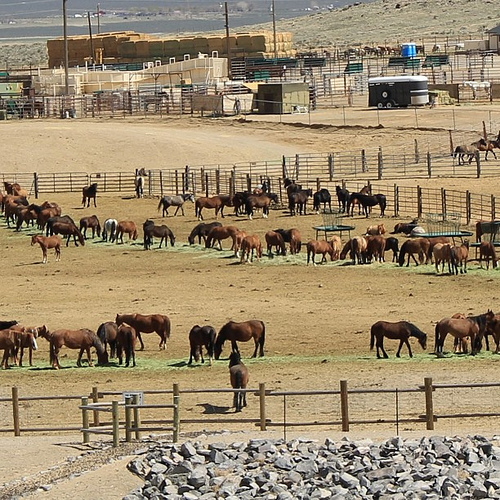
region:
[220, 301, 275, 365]
brown horse in pen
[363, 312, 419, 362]
brown horse in pen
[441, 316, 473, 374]
brown horse in pen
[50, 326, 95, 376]
brown horse in pen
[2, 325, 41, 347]
brown horse in pen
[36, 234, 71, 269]
brown horse in pen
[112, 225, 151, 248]
brown horse in pen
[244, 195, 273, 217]
brown horse in pen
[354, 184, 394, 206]
brown horse in pen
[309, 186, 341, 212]
brown horse in pen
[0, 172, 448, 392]
several horses in a corral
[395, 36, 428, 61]
two blue port a potties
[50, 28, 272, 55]
several stacks of hay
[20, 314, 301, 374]
several horses eating hay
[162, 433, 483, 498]
a huge pile of rocks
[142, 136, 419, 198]
wood fence and post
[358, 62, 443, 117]
a green and white horse trailer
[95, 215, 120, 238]
a white horse with a black tail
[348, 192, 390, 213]
a black horse next to a fence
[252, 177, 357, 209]
several horses standing next to a fence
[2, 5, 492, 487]
horses in a farm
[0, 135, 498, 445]
horses enclose in a pen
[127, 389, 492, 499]
rocks in front a pen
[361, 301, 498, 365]
horses eating grass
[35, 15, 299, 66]
bundles of hay behind the pens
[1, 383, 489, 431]
fence is made with wood poles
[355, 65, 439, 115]
a round container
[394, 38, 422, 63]
the cylinders are blue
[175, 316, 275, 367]
horses eating green grass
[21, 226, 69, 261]
a horse in a pen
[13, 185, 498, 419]
A vast pen containing many horses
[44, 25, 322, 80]
L large plie of rectangular hay bales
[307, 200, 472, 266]
Feeding stations for the horses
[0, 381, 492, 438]
A wooden part of the fence containing the horses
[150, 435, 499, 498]
A field of rocks outside of the fencing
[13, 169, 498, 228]
Metal fencing on the far side of the pen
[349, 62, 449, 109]
A trailer for transporting horses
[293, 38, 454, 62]
Another group of horses in the distance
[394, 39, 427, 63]
Two blue portable outhouses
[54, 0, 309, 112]
Several telephone poles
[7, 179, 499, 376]
A large group of horses.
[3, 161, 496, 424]
Horses are in a fence.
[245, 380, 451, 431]
The fence posts are wooden.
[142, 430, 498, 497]
Rocks outside of the fence.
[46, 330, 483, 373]
Hay on the ground.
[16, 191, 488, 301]
The horses are eating hay.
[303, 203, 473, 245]
Feed holders in the fence.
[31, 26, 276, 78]
Large stacks of hay in the background.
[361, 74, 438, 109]
Horse trailer in the background.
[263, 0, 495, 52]
A large brown hill in the background.